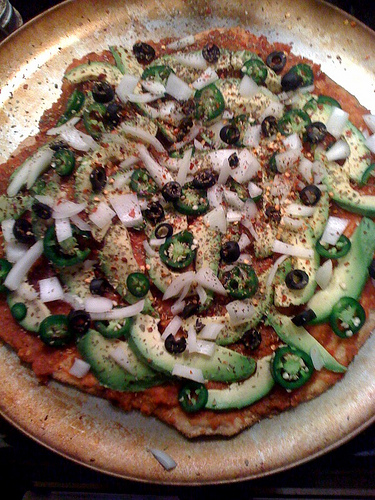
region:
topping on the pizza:
[190, 164, 217, 182]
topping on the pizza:
[181, 390, 204, 409]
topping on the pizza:
[272, 353, 305, 387]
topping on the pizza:
[144, 331, 177, 351]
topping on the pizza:
[107, 354, 126, 373]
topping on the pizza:
[263, 214, 303, 245]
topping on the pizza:
[91, 240, 130, 279]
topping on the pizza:
[106, 205, 147, 245]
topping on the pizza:
[256, 194, 296, 233]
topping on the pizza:
[83, 202, 110, 230]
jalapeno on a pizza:
[172, 180, 213, 213]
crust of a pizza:
[114, 391, 309, 484]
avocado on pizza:
[123, 308, 259, 383]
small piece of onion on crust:
[137, 440, 184, 479]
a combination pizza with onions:
[2, 25, 373, 425]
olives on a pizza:
[161, 326, 189, 354]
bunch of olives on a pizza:
[69, 32, 341, 253]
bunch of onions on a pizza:
[17, 63, 365, 370]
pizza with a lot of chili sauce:
[24, 67, 336, 340]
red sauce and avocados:
[47, 39, 126, 138]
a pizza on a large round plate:
[0, 0, 373, 484]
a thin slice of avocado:
[128, 314, 256, 380]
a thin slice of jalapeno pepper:
[272, 346, 313, 391]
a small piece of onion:
[110, 193, 143, 225]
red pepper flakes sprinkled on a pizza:
[195, 217, 220, 274]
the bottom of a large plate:
[6, 358, 372, 488]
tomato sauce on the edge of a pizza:
[1, 306, 58, 387]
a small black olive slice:
[66, 309, 90, 336]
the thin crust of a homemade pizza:
[164, 412, 261, 441]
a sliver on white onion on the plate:
[152, 447, 177, 470]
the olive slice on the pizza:
[222, 238, 238, 263]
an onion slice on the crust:
[138, 441, 182, 472]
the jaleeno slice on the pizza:
[170, 380, 210, 418]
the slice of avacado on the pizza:
[322, 159, 373, 221]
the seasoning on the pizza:
[208, 118, 334, 328]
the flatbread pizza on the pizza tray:
[3, 22, 374, 440]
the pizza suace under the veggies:
[4, 293, 73, 372]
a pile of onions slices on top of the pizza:
[45, 193, 145, 241]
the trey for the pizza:
[2, 431, 359, 489]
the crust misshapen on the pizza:
[0, 65, 103, 204]